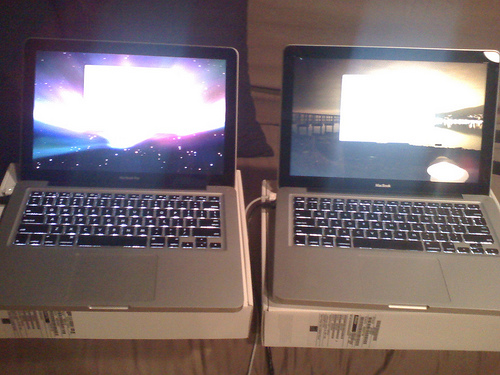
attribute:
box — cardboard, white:
[257, 279, 498, 366]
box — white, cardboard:
[4, 294, 253, 342]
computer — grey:
[269, 40, 498, 315]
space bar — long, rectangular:
[349, 236, 424, 251]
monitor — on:
[274, 39, 499, 202]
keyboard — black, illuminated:
[292, 195, 499, 257]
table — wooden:
[0, 125, 498, 373]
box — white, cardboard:
[5, 310, 260, 341]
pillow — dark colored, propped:
[94, 20, 235, 30]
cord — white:
[246, 327, 261, 374]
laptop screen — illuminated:
[20, 34, 241, 191]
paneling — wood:
[131, 340, 203, 373]